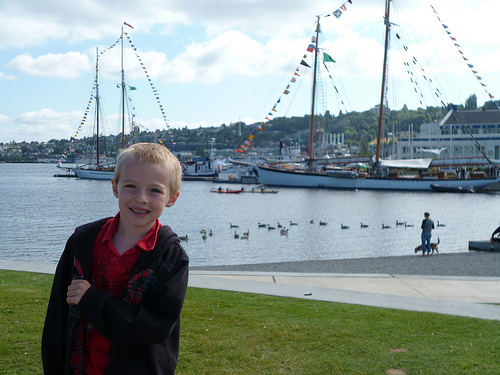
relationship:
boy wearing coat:
[41, 142, 190, 375] [40, 216, 190, 375]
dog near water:
[414, 236, 441, 256] [316, 235, 411, 253]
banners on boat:
[46, 25, 418, 132] [55, 21, 228, 181]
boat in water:
[210, 189, 242, 194] [187, 196, 403, 210]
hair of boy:
[113, 141, 183, 208] [41, 142, 190, 375]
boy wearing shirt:
[22, 128, 214, 373] [70, 209, 163, 373]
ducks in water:
[269, 213, 383, 238] [192, 193, 406, 265]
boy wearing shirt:
[41, 142, 190, 375] [78, 213, 160, 373]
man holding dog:
[420, 211, 435, 256] [413, 236, 445, 256]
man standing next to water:
[420, 211, 435, 256] [1, 160, 483, 266]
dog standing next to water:
[413, 236, 445, 256] [1, 160, 483, 266]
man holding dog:
[420, 211, 435, 256] [413, 236, 441, 257]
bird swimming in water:
[232, 230, 239, 240] [1, 160, 483, 266]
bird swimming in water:
[317, 219, 328, 228] [1, 160, 483, 266]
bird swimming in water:
[379, 221, 391, 231] [1, 160, 483, 266]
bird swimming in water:
[227, 220, 240, 227] [1, 160, 483, 266]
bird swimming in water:
[200, 230, 209, 241] [1, 160, 483, 266]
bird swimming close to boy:
[232, 230, 239, 240] [41, 142, 190, 375]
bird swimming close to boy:
[317, 219, 328, 228] [41, 142, 190, 375]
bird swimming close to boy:
[379, 221, 391, 231] [41, 142, 190, 375]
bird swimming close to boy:
[227, 220, 240, 227] [41, 142, 190, 375]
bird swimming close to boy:
[200, 230, 209, 241] [41, 142, 190, 375]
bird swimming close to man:
[232, 230, 239, 240] [420, 211, 435, 256]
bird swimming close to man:
[317, 219, 328, 228] [420, 211, 435, 256]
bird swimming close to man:
[379, 221, 391, 231] [420, 211, 435, 256]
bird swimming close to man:
[227, 220, 240, 227] [420, 211, 435, 256]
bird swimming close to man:
[200, 230, 209, 241] [420, 211, 435, 256]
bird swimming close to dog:
[232, 230, 239, 240] [413, 236, 441, 257]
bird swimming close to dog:
[317, 219, 328, 228] [413, 236, 441, 257]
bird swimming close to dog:
[379, 221, 391, 231] [413, 236, 441, 257]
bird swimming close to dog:
[227, 220, 240, 227] [413, 236, 441, 257]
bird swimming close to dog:
[200, 230, 209, 241] [413, 236, 441, 257]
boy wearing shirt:
[41, 142, 190, 375] [70, 209, 163, 373]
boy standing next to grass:
[41, 142, 190, 375] [169, 292, 489, 365]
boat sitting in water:
[208, 184, 244, 194] [1, 160, 483, 266]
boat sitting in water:
[240, 187, 280, 195] [1, 160, 483, 266]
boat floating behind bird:
[208, 184, 244, 194] [317, 219, 329, 226]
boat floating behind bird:
[208, 184, 244, 194] [358, 220, 369, 230]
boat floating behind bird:
[208, 184, 244, 194] [255, 220, 267, 229]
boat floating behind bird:
[208, 184, 244, 194] [200, 232, 207, 241]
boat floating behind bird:
[208, 184, 244, 194] [401, 220, 415, 230]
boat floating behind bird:
[240, 187, 280, 195] [317, 219, 329, 226]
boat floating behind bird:
[240, 187, 280, 195] [358, 220, 369, 230]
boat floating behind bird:
[240, 187, 280, 195] [255, 220, 267, 229]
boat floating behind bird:
[240, 187, 280, 195] [200, 232, 207, 241]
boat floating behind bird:
[240, 187, 280, 195] [401, 220, 415, 230]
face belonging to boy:
[115, 160, 171, 225] [41, 142, 190, 375]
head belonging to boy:
[109, 139, 183, 226] [41, 142, 190, 375]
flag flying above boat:
[321, 50, 336, 69] [250, 161, 499, 190]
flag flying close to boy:
[321, 50, 336, 69] [41, 142, 190, 375]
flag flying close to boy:
[121, 20, 134, 29] [41, 142, 190, 375]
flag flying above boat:
[121, 20, 134, 29] [55, 22, 217, 183]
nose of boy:
[138, 193, 147, 209] [41, 142, 190, 375]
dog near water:
[414, 236, 441, 256] [294, 192, 367, 223]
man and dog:
[414, 206, 437, 250] [409, 238, 442, 254]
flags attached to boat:
[249, 14, 484, 174] [248, 132, 478, 198]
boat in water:
[210, 189, 242, 194] [4, 154, 494, 256]